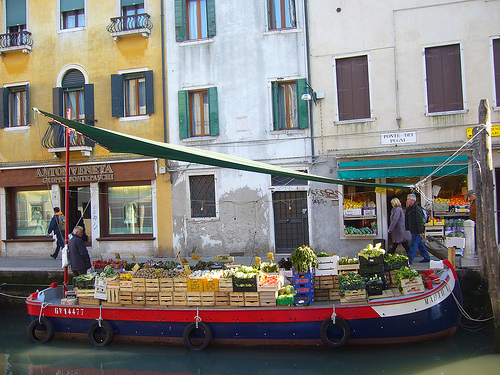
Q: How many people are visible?
A: 4.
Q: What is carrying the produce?
A: Boat.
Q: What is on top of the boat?
A: Produce.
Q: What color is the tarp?
A: Green.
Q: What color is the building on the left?
A: Yellow.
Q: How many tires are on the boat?
A: 4.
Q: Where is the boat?
A: On the water.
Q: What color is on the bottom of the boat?
A: Blue.